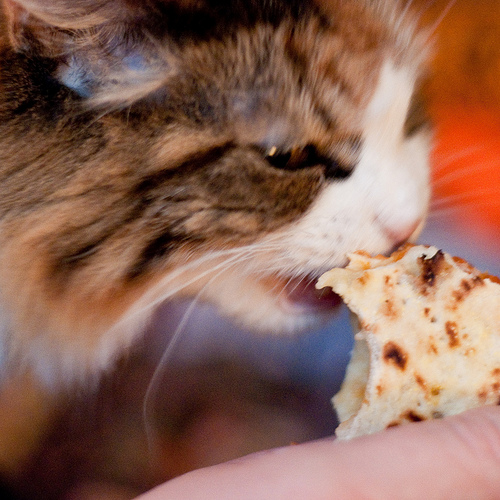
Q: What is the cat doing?
A: Feeding.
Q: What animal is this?
A: Cat.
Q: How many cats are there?
A: One.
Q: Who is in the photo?
A: No one.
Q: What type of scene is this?
A: Indoor.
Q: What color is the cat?
A: Brown,black and white.